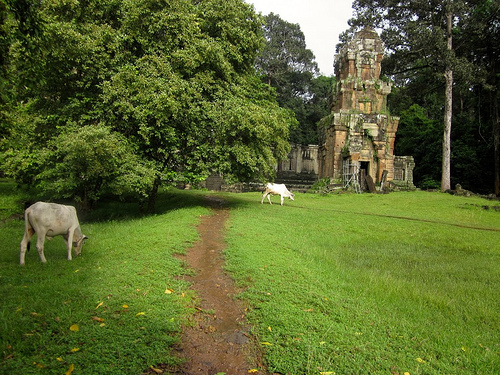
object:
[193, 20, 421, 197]
structure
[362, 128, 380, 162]
moss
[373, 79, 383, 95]
moss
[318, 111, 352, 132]
moss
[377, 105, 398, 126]
moss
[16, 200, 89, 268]
cow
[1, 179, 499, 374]
grass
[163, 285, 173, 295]
leaf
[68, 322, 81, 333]
leaf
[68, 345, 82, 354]
leaf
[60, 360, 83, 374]
leaf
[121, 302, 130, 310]
leaf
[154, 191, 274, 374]
path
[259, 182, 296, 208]
cow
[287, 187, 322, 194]
step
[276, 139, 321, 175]
building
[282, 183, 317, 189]
step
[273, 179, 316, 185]
step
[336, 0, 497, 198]
tree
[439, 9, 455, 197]
trunk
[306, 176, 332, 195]
shrubbery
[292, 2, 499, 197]
wooded area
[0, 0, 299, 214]
tree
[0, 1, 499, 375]
countryside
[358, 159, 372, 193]
door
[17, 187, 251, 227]
shadow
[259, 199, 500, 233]
shadow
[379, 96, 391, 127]
ivy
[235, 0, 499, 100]
sky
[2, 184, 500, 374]
field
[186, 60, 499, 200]
background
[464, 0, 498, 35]
leaves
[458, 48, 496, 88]
leaves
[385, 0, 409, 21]
leaves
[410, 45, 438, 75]
leaves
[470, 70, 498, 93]
leaves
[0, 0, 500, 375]
image